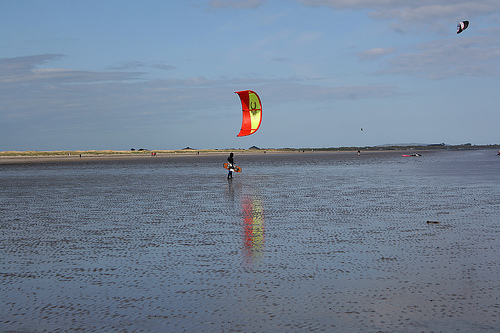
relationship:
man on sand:
[221, 148, 242, 182] [206, 171, 257, 187]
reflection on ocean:
[236, 193, 276, 258] [0, 152, 498, 332]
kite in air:
[408, 13, 499, 54] [202, 73, 362, 146]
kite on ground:
[400, 152, 421, 159] [0, 150, 450, 162]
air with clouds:
[0, 0, 499, 153] [10, 57, 265, 131]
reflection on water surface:
[241, 196, 265, 265] [2, 152, 497, 330]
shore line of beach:
[6, 152, 421, 156] [11, 147, 467, 153]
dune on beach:
[175, 143, 213, 158] [12, 144, 497, 180]